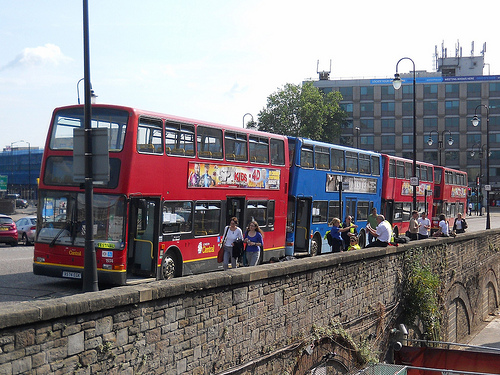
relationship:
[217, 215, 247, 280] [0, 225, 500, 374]
person sitting on wall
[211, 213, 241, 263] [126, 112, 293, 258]
woman walking on side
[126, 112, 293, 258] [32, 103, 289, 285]
side of bus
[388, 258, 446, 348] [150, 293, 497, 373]
bush on side of wall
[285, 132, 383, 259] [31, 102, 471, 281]
section of this doubledeckered bus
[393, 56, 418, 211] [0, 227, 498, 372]
lamp on th bridge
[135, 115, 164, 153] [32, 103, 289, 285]
window of a bus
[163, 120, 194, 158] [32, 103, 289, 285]
window of a bus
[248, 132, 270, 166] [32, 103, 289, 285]
window of a bus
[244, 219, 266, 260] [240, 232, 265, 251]
woman wearing a shirt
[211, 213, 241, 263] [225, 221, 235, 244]
woman wearing a sweater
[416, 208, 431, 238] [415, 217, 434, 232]
man wearing a shirt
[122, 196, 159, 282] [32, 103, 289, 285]
door of bus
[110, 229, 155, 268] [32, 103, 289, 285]
railing up bus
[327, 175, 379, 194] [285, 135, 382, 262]
banner on bus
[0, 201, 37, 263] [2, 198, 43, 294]
cars on lot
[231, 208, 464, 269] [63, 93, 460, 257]
people next to bus